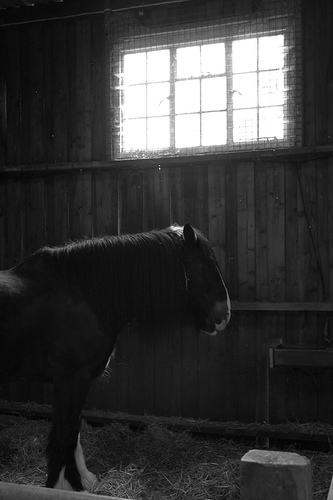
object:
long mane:
[22, 229, 189, 356]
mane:
[79, 242, 195, 284]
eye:
[191, 258, 205, 273]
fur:
[115, 242, 147, 287]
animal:
[10, 220, 241, 486]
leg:
[38, 378, 96, 486]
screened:
[96, 15, 306, 157]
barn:
[1, 11, 329, 494]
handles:
[156, 87, 243, 107]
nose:
[208, 304, 227, 332]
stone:
[223, 441, 312, 490]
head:
[128, 210, 258, 333]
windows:
[116, 30, 287, 155]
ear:
[181, 221, 199, 245]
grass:
[118, 449, 201, 498]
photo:
[6, 16, 329, 387]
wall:
[0, 0, 331, 448]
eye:
[202, 253, 215, 267]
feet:
[45, 458, 98, 490]